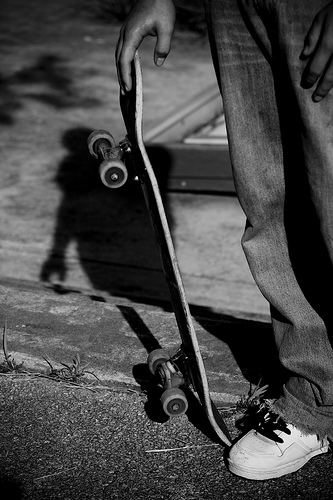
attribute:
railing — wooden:
[117, 73, 246, 203]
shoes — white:
[233, 399, 322, 492]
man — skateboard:
[108, 0, 332, 482]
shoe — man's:
[226, 405, 331, 484]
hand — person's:
[100, 1, 193, 96]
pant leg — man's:
[205, 1, 332, 424]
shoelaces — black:
[253, 402, 289, 441]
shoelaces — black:
[236, 405, 293, 442]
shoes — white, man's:
[212, 404, 331, 481]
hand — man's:
[114, 0, 182, 94]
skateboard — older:
[91, 47, 238, 445]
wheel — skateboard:
[145, 350, 189, 421]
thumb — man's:
[151, 25, 191, 64]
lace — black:
[248, 410, 290, 447]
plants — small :
[1, 311, 102, 386]